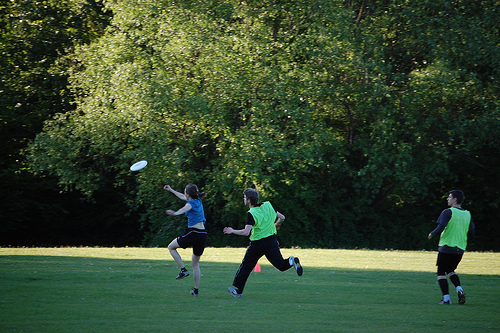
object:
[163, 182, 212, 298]
man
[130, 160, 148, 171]
frisbee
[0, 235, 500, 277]
sun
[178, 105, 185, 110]
leaves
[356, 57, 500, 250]
trees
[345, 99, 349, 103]
leaves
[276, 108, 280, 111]
leaves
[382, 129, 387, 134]
leaves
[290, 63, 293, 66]
leaves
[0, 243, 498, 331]
field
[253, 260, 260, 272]
cone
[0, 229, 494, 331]
ground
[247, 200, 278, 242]
shirts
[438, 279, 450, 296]
socks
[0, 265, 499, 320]
shadow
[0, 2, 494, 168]
air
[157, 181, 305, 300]
two people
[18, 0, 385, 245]
green trees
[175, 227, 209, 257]
shorts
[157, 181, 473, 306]
three people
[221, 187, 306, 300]
another man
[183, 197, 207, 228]
blue shirt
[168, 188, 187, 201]
arm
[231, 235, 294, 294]
black pants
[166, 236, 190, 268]
raised leg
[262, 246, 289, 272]
bent leg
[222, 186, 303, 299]
man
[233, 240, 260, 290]
straight leg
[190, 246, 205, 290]
straight leg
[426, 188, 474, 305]
man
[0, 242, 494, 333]
grass